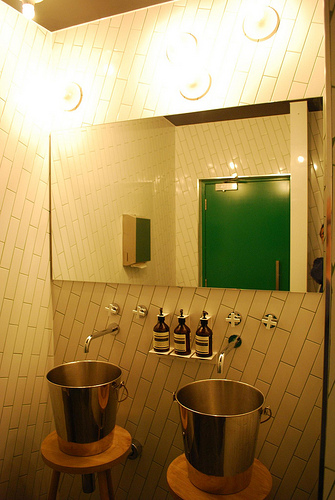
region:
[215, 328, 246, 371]
a faucet on the wall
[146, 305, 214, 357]
three brown dispensers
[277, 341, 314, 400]
tile on a wall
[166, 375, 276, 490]
a metal bucket sink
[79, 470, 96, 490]
the drain on a sink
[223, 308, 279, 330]
knobs for a water faucet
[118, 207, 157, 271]
a paper towel dispenser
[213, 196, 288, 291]
a green painted door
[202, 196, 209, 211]
a door hinge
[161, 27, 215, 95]
lights on the wall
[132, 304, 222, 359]
three bottles on the shelf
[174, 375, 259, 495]
silver bucket on stool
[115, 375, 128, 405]
handle of bucket to the side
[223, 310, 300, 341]
hot and cold handles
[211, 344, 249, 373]
faucet from the wall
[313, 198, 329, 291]
person in the mirror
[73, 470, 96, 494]
metal object under stool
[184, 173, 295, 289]
large green door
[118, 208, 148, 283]
towel dispenser on the wall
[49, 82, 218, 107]
two lights on the wall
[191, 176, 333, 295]
A green door is reflecting from a mirror.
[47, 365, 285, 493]
Two buckets are on top of a stool.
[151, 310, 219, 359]
3 bottles are hanging from a wall.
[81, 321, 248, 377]
Two faucets are coming out of the wall.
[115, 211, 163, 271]
Paper towel dispenser is reflecting from a mirror.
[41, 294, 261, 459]
The sinks are underneath a mirror.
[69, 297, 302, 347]
Sink knobs are underneath the mirror.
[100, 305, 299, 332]
Sink knobs are coming out of the wall.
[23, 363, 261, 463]
2 silver buckets are under the mirror.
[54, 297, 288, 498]
White tile is displayed behind the buckets.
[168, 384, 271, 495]
the bucket is mettalic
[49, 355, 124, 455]
the bucket is metallic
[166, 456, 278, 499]
the stool is wooden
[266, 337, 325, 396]
the walls are tiled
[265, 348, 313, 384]
the tiles are white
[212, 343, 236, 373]
the tap is mettalic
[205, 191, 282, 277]
the door is blue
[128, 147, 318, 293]
reflection is in the mirror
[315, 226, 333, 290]
the guy is in the mirror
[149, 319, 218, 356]
the bottles are three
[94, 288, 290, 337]
Knobs on the wall.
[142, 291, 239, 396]
Soap on the ledge.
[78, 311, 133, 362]
Faucet on the wall.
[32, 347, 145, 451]
Bucket on the stool.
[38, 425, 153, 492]
Stool with a bucket.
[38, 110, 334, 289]
Mirror on the wall.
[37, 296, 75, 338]
Tile on the wall.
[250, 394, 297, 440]
Handle on the bucket.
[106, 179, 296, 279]
Reflection in the mirror.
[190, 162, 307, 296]
Green door reflected in the mirror.